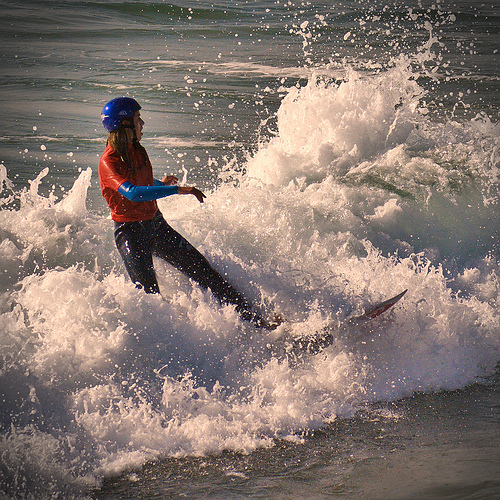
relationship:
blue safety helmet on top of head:
[87, 80, 156, 146] [101, 95, 133, 140]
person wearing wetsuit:
[97, 98, 283, 335] [78, 89, 323, 355]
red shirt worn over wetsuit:
[91, 139, 165, 230] [99, 146, 276, 336]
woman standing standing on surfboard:
[61, 84, 301, 355] [278, 293, 399, 353]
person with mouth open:
[97, 98, 283, 335] [135, 125, 151, 137]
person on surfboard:
[97, 98, 283, 335] [239, 275, 433, 368]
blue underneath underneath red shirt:
[98, 156, 229, 218] [97, 141, 162, 226]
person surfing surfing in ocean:
[90, 91, 402, 379] [36, 71, 500, 495]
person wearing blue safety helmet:
[97, 98, 283, 335] [100, 95, 140, 132]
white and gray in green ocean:
[20, 19, 499, 490] [2, 3, 498, 500]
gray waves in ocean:
[160, 24, 301, 140] [27, 20, 484, 478]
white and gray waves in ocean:
[167, 27, 499, 394] [27, 20, 484, 478]